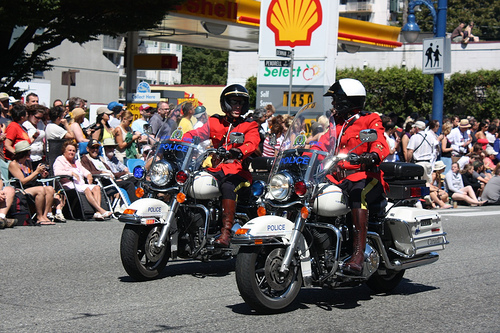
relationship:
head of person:
[216, 74, 273, 122] [211, 105, 263, 189]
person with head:
[211, 105, 263, 189] [216, 74, 273, 122]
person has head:
[211, 105, 263, 189] [216, 74, 273, 122]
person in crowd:
[211, 105, 263, 189] [43, 111, 208, 198]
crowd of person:
[43, 111, 208, 198] [211, 105, 263, 189]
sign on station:
[261, 21, 320, 52] [161, 32, 345, 112]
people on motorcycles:
[389, 117, 463, 161] [152, 181, 299, 244]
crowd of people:
[43, 111, 208, 198] [389, 117, 463, 161]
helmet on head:
[201, 93, 271, 123] [216, 74, 273, 122]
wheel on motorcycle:
[111, 221, 177, 274] [224, 75, 464, 315]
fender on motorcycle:
[126, 169, 181, 232] [105, 96, 327, 288]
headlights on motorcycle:
[122, 164, 198, 184] [230, 99, 460, 313]